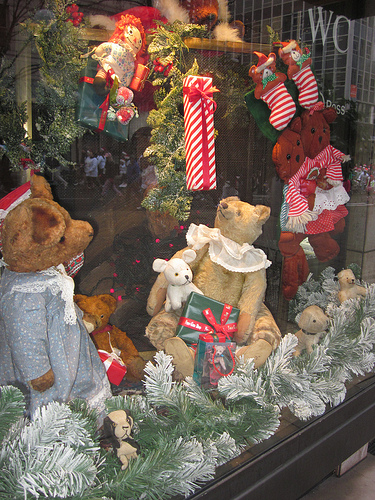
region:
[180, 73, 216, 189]
a tall red and white gift package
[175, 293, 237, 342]
a green and red gift wrapped package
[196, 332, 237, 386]
a Christmas gift bag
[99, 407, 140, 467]
a plush dog doll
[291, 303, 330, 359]
a plush dog doll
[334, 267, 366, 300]
a plush teddy bear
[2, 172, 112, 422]
a teddy bear with dress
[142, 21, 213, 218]
a green Christmas garland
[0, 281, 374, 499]
a green Christmas garland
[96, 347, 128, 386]
a red and white gift package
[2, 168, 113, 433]
The teddy bear is brown.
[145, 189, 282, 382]
The teddy bear is brown.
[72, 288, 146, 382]
The teddy bear is brown.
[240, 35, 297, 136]
The stocking is striped.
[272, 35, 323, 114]
The stocking is striped.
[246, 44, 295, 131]
The stocking has a teddy bear head.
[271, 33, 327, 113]
The stocking has a teddy bear head.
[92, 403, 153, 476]
The dog is black and tan.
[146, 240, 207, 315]
The dog is white.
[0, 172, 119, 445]
The teddy bear is wearing a dress.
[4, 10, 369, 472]
A store window Christmas display.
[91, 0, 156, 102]
A Raggedy Ann doll.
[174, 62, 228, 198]
A red and white wrapped present.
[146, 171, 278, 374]
A large tan teddy bear on the right.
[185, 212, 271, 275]
Lace collar around a teddy bear's neck.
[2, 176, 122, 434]
A large brown teddy bear.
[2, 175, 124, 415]
A teddy bear wearing a blue and white outfit.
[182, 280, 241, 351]
A present wrapped in green with a red bow.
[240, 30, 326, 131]
Two red and white striped Christmas stockings.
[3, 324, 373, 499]
A green pine Christmas garland.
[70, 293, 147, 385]
a brown teddy bear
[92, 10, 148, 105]
a Raggedy Anne doll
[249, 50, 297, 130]
a teddy bear in stocking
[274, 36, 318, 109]
a teddy bear in stocking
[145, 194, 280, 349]
a large tan teddy bear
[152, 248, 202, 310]
a white plush dog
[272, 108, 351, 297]
two dark brown teddy bears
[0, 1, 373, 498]
a store front window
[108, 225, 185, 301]
a roll of red Christmas lights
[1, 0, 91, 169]
a green Christmas wreath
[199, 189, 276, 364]
bear in a window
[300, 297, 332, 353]
dog in a window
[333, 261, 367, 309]
bear in a window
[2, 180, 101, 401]
bear in a window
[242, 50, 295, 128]
bear in a window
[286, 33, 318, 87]
bear in a window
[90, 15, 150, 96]
doll in a window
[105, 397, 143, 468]
dog in a window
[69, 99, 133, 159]
present in a window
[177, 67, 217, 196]
present in a window